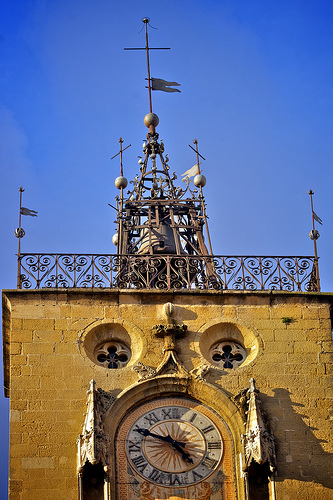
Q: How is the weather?
A: It is clear.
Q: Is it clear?
A: Yes, it is clear.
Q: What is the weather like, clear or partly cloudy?
A: It is clear.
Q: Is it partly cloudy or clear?
A: It is clear.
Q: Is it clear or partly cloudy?
A: It is clear.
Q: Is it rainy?
A: No, it is clear.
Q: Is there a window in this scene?
A: Yes, there is a window.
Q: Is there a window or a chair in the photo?
A: Yes, there is a window.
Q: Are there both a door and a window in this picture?
A: Yes, there are both a window and a door.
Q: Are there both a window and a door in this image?
A: Yes, there are both a window and a door.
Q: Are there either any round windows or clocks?
A: Yes, there is a round window.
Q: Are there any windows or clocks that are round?
A: Yes, the window is round.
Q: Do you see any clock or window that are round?
A: Yes, the window is round.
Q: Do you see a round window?
A: Yes, there is a round window.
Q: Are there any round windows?
A: Yes, there is a round window.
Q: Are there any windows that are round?
A: Yes, there is a window that is round.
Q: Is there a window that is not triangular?
A: Yes, there is a round window.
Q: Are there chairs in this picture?
A: No, there are no chairs.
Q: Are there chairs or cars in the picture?
A: No, there are no chairs or cars.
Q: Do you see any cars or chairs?
A: No, there are no chairs or cars.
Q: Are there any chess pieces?
A: No, there are no chess pieces.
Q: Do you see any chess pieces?
A: No, there are no chess pieces.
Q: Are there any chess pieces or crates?
A: No, there are no chess pieces or crates.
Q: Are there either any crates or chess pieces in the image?
A: No, there are no chess pieces or crates.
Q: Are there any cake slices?
A: No, there are no cake slices.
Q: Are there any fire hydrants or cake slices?
A: No, there are no cake slices or fire hydrants.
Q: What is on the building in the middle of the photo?
A: The bell is on the tower.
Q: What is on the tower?
A: The bell is on the tower.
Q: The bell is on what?
A: The bell is on the tower.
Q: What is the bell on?
A: The bell is on the tower.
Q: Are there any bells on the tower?
A: Yes, there is a bell on the tower.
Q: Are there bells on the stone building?
A: Yes, there is a bell on the tower.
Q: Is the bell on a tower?
A: Yes, the bell is on a tower.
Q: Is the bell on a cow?
A: No, the bell is on a tower.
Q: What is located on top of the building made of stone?
A: The bell is on top of the tower.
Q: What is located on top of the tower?
A: The bell is on top of the tower.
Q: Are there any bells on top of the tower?
A: Yes, there is a bell on top of the tower.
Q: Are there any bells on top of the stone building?
A: Yes, there is a bell on top of the tower.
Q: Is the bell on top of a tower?
A: Yes, the bell is on top of a tower.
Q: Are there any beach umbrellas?
A: No, there are no beach umbrellas.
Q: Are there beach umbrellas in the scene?
A: No, there are no beach umbrellas.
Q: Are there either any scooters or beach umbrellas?
A: No, there are no beach umbrellas or scooters.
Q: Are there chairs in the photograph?
A: No, there are no chairs.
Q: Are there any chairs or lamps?
A: No, there are no chairs or lamps.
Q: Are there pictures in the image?
A: No, there are no pictures.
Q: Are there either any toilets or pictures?
A: No, there are no pictures or toilets.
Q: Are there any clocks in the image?
A: Yes, there is a clock.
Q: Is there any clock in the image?
A: Yes, there is a clock.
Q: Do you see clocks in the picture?
A: Yes, there is a clock.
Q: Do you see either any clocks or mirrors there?
A: Yes, there is a clock.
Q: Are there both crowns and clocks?
A: No, there is a clock but no crowns.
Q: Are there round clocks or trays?
A: Yes, there is a round clock.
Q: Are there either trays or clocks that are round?
A: Yes, the clock is round.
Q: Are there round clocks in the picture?
A: Yes, there is a round clock.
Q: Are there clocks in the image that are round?
A: Yes, there is a clock that is round.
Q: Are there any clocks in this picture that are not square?
A: Yes, there is a round clock.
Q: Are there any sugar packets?
A: No, there are no sugar packets.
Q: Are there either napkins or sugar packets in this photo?
A: No, there are no sugar packets or napkins.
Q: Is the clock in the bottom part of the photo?
A: Yes, the clock is in the bottom of the image.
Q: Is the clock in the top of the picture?
A: No, the clock is in the bottom of the image.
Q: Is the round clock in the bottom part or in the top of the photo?
A: The clock is in the bottom of the image.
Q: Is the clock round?
A: Yes, the clock is round.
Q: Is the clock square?
A: No, the clock is round.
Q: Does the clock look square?
A: No, the clock is round.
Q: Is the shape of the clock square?
A: No, the clock is round.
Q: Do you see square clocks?
A: No, there is a clock but it is round.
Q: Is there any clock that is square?
A: No, there is a clock but it is round.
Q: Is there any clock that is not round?
A: No, there is a clock but it is round.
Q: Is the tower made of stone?
A: Yes, the tower is made of stone.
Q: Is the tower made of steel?
A: No, the tower is made of stone.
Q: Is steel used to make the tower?
A: No, the tower is made of stone.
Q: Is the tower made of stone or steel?
A: The tower is made of stone.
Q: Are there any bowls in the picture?
A: No, there are no bowls.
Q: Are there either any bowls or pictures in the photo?
A: No, there are no bowls or pictures.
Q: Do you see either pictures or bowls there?
A: No, there are no bowls or pictures.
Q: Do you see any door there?
A: Yes, there is a door.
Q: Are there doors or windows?
A: Yes, there is a door.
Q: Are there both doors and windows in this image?
A: Yes, there are both a door and windows.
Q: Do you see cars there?
A: No, there are no cars.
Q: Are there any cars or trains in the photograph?
A: No, there are no cars or trains.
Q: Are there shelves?
A: No, there are no shelves.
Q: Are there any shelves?
A: No, there are no shelves.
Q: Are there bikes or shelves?
A: No, there are no shelves or bikes.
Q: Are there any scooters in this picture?
A: No, there are no scooters.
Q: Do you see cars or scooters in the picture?
A: No, there are no scooters or cars.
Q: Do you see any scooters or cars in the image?
A: No, there are no scooters or cars.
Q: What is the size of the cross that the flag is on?
A: The cross is large.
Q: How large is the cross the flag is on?
A: The cross is large.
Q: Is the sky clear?
A: Yes, the sky is clear.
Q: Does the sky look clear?
A: Yes, the sky is clear.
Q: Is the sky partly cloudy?
A: No, the sky is clear.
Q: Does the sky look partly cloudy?
A: No, the sky is clear.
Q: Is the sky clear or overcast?
A: The sky is clear.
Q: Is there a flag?
A: Yes, there is a flag.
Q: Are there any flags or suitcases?
A: Yes, there is a flag.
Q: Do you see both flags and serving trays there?
A: No, there is a flag but no serving trays.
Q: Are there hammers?
A: No, there are no hammers.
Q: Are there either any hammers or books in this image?
A: No, there are no hammers or books.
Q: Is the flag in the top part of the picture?
A: Yes, the flag is in the top of the image.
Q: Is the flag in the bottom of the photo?
A: No, the flag is in the top of the image.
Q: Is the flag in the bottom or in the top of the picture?
A: The flag is in the top of the image.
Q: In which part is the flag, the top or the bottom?
A: The flag is in the top of the image.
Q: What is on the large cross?
A: The flag is on the cross.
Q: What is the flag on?
A: The flag is on the cross.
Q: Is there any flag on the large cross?
A: Yes, there is a flag on the cross.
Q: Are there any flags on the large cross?
A: Yes, there is a flag on the cross.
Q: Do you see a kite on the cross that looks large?
A: No, there is a flag on the cross.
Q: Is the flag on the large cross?
A: Yes, the flag is on the cross.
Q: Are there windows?
A: Yes, there is a window.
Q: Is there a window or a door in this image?
A: Yes, there is a window.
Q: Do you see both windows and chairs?
A: No, there is a window but no chairs.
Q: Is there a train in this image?
A: No, there are no trains.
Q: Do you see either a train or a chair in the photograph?
A: No, there are no trains or chairs.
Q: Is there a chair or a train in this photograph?
A: No, there are no trains or chairs.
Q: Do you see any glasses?
A: No, there are no glasses.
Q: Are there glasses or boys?
A: No, there are no glasses or boys.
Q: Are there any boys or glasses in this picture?
A: No, there are no glasses or boys.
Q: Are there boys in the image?
A: No, there are no boys.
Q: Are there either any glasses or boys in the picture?
A: No, there are no boys or glasses.